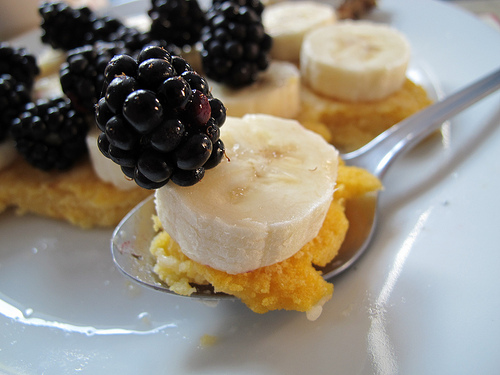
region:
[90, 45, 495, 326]
a spoonful of a fruit topped fritter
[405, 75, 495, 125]
the handle of a spoon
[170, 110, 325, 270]
a slice of sweet banana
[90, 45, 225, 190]
a juicy blackberry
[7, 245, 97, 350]
a white ceramic dish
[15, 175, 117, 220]
a crispy fritter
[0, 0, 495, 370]
a delicious breakfast plate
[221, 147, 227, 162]
the small stem of a blackberry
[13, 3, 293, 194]
berries stacked on top of bananas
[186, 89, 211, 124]
a less ripe segment of a blackberry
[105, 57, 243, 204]
blackberry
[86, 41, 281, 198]
one blackberry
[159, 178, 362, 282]
banana slice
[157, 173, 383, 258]
one banana slice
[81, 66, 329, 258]
one blackberry on one banana slice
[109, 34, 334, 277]
blackberry and banana slice on spoon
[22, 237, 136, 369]
plate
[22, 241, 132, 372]
white plate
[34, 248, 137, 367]
glass white plate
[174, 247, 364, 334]
yellow crust on spoon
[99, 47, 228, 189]
black raspberry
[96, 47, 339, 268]
Banana with raspberry on top.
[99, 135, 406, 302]
Spoon with food on it.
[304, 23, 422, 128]
Pancake with a banana slice.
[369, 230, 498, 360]
A white plate.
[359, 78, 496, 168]
Silver spoon handle.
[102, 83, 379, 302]
Pancake with banana and raspberry on top.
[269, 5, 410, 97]
Two banana slices.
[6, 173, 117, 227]
Pancake is on the plate.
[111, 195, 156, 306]
The tip of the spoon.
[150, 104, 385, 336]
banana is sliced thick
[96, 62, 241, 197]
blackberry on top of banana